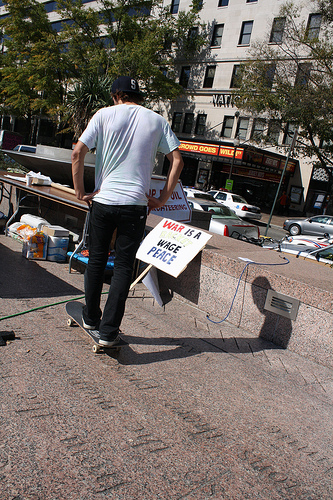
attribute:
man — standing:
[76, 74, 184, 345]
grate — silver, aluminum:
[263, 289, 304, 322]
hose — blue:
[203, 249, 293, 326]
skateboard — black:
[60, 294, 131, 359]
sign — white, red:
[138, 216, 211, 276]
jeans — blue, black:
[77, 201, 145, 349]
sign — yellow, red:
[177, 141, 243, 159]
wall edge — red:
[222, 235, 332, 289]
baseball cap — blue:
[108, 73, 150, 98]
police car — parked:
[208, 186, 260, 222]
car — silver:
[285, 209, 332, 236]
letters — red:
[162, 219, 183, 233]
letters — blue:
[144, 244, 179, 269]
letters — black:
[156, 234, 184, 253]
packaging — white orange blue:
[4, 220, 51, 259]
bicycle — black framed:
[230, 216, 298, 249]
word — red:
[163, 218, 189, 236]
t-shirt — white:
[84, 98, 181, 209]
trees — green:
[10, 6, 88, 119]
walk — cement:
[164, 329, 261, 427]